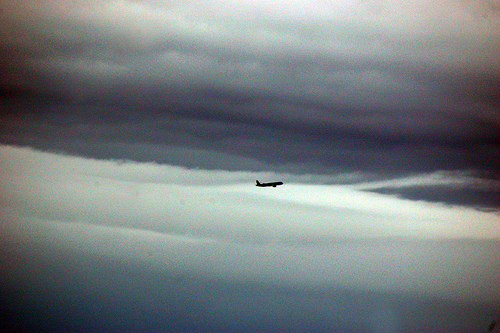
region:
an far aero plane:
[230, 152, 324, 224]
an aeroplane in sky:
[224, 154, 334, 219]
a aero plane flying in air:
[204, 132, 341, 243]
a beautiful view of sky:
[26, 36, 498, 230]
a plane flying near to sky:
[21, 37, 466, 330]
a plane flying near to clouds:
[51, 44, 398, 252]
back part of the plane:
[253, 171, 261, 194]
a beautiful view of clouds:
[43, 33, 491, 209]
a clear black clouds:
[21, 19, 487, 233]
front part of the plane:
[278, 167, 291, 199]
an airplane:
[241, 173, 295, 198]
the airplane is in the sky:
[235, 164, 315, 214]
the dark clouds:
[67, 76, 354, 165]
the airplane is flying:
[248, 166, 298, 199]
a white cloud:
[329, 184, 420, 214]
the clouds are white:
[122, 8, 337, 37]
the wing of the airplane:
[270, 182, 276, 187]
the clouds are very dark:
[43, 269, 243, 331]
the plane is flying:
[236, 164, 327, 217]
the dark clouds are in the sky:
[33, 85, 263, 162]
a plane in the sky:
[251, 170, 303, 204]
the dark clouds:
[41, 91, 196, 156]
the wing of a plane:
[268, 181, 280, 190]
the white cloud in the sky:
[335, 135, 499, 194]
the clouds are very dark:
[46, 19, 262, 96]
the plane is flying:
[236, 177, 304, 202]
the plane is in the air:
[243, 161, 295, 210]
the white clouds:
[57, 167, 203, 242]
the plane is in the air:
[252, 172, 316, 205]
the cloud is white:
[360, 201, 468, 247]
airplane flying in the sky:
[237, 135, 294, 245]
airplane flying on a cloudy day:
[35, 86, 481, 263]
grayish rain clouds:
[88, 22, 454, 164]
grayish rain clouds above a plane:
[151, 12, 411, 233]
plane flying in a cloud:
[75, 163, 396, 324]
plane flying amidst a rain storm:
[7, 2, 494, 316]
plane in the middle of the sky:
[149, 131, 498, 308]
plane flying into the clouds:
[92, 0, 331, 227]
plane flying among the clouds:
[27, 16, 457, 319]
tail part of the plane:
[245, 153, 264, 192]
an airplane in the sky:
[172, 85, 461, 277]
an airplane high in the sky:
[164, 104, 419, 274]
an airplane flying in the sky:
[77, 68, 497, 310]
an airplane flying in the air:
[169, 79, 436, 310]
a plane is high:
[114, 48, 456, 307]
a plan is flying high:
[174, 102, 464, 257]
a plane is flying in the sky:
[176, 95, 358, 250]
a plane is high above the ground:
[129, 78, 396, 277]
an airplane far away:
[183, 14, 371, 285]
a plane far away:
[194, 92, 433, 331]